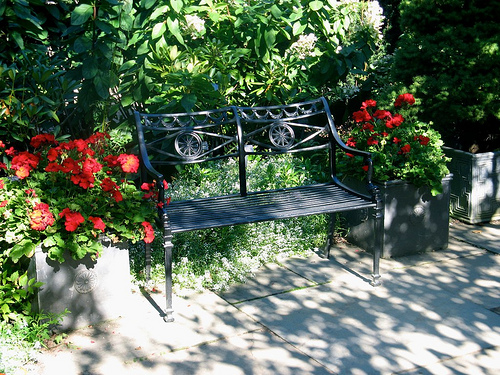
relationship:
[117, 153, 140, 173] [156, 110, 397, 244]
flower besides bench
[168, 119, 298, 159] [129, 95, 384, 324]
wheel on bench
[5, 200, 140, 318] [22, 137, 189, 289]
design on planter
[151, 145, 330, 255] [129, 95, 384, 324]
bush behind bench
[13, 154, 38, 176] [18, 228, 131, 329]
flower in garden box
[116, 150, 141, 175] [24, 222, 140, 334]
flower in garden box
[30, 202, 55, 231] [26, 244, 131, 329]
flower in garden box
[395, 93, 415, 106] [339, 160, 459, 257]
flower in garden box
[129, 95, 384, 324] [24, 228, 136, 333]
bench between box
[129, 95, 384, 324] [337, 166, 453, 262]
bench between box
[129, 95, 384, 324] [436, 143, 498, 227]
bench between box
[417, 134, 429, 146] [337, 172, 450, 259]
flower in box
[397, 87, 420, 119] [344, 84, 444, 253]
flower in garden box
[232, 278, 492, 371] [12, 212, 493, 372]
stone on sidewalk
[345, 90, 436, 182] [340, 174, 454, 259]
rose bush in box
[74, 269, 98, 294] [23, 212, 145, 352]
design on planter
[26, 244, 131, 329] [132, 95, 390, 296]
garden box next to bench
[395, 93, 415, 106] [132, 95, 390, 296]
flower growing next to bench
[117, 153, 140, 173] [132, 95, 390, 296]
flower growing next to bench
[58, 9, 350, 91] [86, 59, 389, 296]
plants growing behind bench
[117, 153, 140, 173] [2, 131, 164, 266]
flower on bush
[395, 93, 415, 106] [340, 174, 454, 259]
flower in box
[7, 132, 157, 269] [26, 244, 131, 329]
flower in garden box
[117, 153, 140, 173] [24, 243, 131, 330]
flower in pot